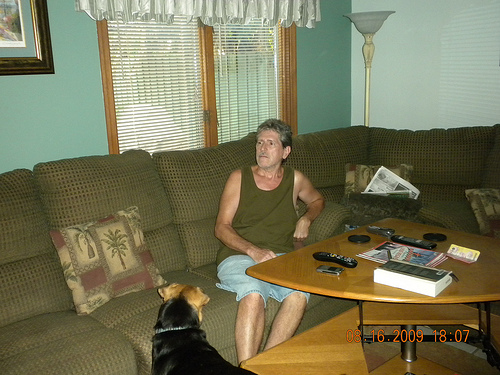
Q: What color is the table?
A: Brown.